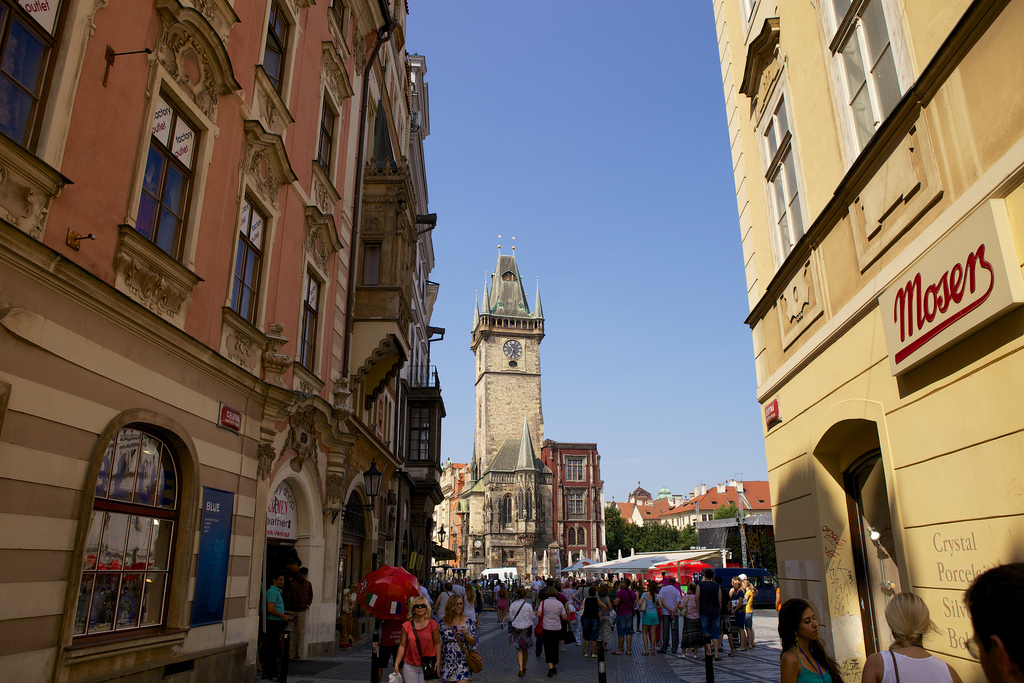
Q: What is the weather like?
A: It is clear.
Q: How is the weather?
A: It is clear.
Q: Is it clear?
A: Yes, it is clear.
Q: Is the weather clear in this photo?
A: Yes, it is clear.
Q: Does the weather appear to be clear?
A: Yes, it is clear.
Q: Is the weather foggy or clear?
A: It is clear.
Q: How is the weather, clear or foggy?
A: It is clear.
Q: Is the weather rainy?
A: No, it is clear.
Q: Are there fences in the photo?
A: No, there are no fences.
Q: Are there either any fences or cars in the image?
A: No, there are no fences or cars.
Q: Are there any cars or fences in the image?
A: No, there are no fences or cars.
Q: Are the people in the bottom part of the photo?
A: Yes, the people are in the bottom of the image.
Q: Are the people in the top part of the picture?
A: No, the people are in the bottom of the image.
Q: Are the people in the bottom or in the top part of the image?
A: The people are in the bottom of the image.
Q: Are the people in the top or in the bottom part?
A: The people are in the bottom of the image.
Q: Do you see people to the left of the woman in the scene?
A: Yes, there are people to the left of the woman.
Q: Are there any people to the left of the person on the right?
A: Yes, there are people to the left of the woman.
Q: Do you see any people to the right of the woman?
A: No, the people are to the left of the woman.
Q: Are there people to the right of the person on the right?
A: No, the people are to the left of the woman.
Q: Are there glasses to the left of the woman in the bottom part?
A: No, there are people to the left of the woman.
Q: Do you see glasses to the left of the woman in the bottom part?
A: No, there are people to the left of the woman.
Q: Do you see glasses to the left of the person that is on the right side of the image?
A: No, there are people to the left of the woman.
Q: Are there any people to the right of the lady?
A: Yes, there are people to the right of the lady.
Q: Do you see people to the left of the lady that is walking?
A: No, the people are to the right of the lady.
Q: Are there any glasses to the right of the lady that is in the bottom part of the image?
A: No, there are people to the right of the lady.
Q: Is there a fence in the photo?
A: No, there are no fences.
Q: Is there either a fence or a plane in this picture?
A: No, there are no fences or airplanes.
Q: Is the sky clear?
A: Yes, the sky is clear.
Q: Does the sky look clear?
A: Yes, the sky is clear.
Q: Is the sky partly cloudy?
A: No, the sky is clear.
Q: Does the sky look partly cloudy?
A: No, the sky is clear.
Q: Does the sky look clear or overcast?
A: The sky is clear.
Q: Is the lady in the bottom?
A: Yes, the lady is in the bottom of the image.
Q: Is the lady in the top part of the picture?
A: No, the lady is in the bottom of the image.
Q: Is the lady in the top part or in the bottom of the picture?
A: The lady is in the bottom of the image.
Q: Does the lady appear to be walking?
A: Yes, the lady is walking.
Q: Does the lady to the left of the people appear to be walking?
A: Yes, the lady is walking.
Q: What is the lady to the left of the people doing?
A: The lady is walking.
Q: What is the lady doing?
A: The lady is walking.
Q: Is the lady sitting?
A: No, the lady is walking.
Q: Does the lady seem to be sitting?
A: No, the lady is walking.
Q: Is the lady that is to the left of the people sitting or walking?
A: The lady is walking.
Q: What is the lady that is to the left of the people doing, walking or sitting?
A: The lady is walking.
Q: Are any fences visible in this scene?
A: No, there are no fences.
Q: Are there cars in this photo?
A: No, there are no cars.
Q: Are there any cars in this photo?
A: No, there are no cars.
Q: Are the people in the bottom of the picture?
A: Yes, the people are in the bottom of the image.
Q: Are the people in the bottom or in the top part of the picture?
A: The people are in the bottom of the image.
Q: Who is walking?
A: The people are walking.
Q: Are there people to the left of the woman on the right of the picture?
A: Yes, there are people to the left of the woman.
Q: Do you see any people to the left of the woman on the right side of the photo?
A: Yes, there are people to the left of the woman.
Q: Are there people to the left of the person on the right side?
A: Yes, there are people to the left of the woman.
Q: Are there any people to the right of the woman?
A: No, the people are to the left of the woman.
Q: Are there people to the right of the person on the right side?
A: No, the people are to the left of the woman.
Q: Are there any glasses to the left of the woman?
A: No, there are people to the left of the woman.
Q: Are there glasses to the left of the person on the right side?
A: No, there are people to the left of the woman.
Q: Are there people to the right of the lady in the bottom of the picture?
A: Yes, there are people to the right of the lady.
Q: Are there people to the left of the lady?
A: No, the people are to the right of the lady.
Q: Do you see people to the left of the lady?
A: No, the people are to the right of the lady.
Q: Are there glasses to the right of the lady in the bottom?
A: No, there are people to the right of the lady.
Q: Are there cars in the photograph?
A: No, there are no cars.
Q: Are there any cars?
A: No, there are no cars.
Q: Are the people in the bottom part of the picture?
A: Yes, the people are in the bottom of the image.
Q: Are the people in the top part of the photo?
A: No, the people are in the bottom of the image.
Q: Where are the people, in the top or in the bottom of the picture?
A: The people are in the bottom of the image.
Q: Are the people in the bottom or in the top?
A: The people are in the bottom of the image.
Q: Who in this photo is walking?
A: The people are walking.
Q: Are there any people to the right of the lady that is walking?
A: Yes, there are people to the right of the lady.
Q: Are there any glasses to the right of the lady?
A: No, there are people to the right of the lady.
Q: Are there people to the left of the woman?
A: Yes, there are people to the left of the woman.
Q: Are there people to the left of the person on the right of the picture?
A: Yes, there are people to the left of the woman.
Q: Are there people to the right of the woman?
A: No, the people are to the left of the woman.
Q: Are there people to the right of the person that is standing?
A: No, the people are to the left of the woman.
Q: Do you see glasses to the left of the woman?
A: No, there are people to the left of the woman.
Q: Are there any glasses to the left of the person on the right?
A: No, there are people to the left of the woman.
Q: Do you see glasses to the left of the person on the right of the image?
A: No, there are people to the left of the woman.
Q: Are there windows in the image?
A: Yes, there is a window.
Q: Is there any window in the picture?
A: Yes, there is a window.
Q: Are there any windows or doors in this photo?
A: Yes, there is a window.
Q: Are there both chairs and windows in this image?
A: No, there is a window but no chairs.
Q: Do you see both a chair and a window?
A: No, there is a window but no chairs.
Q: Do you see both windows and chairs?
A: No, there is a window but no chairs.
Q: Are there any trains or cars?
A: No, there are no cars or trains.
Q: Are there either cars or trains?
A: No, there are no cars or trains.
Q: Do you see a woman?
A: Yes, there is a woman.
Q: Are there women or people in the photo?
A: Yes, there is a woman.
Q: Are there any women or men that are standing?
A: Yes, the woman is standing.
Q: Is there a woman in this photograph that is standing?
A: Yes, there is a woman that is standing.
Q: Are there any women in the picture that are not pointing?
A: Yes, there is a woman that is standing.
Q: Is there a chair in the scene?
A: No, there are no chairs.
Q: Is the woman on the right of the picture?
A: Yes, the woman is on the right of the image.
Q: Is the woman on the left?
A: No, the woman is on the right of the image.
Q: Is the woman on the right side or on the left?
A: The woman is on the right of the image.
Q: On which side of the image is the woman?
A: The woman is on the right of the image.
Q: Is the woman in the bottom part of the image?
A: Yes, the woman is in the bottom of the image.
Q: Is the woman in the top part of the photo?
A: No, the woman is in the bottom of the image.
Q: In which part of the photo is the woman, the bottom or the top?
A: The woman is in the bottom of the image.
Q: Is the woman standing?
A: Yes, the woman is standing.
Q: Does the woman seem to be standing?
A: Yes, the woman is standing.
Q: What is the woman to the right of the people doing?
A: The woman is standing.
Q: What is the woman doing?
A: The woman is standing.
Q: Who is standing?
A: The woman is standing.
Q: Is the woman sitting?
A: No, the woman is standing.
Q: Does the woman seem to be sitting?
A: No, the woman is standing.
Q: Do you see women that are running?
A: No, there is a woman but she is standing.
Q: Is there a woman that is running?
A: No, there is a woman but she is standing.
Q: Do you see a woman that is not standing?
A: No, there is a woman but she is standing.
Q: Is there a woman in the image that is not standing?
A: No, there is a woman but she is standing.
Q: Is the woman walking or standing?
A: The woman is standing.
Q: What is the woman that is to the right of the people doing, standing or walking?
A: The woman is standing.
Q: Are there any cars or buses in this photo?
A: No, there are no cars or buses.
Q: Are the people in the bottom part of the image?
A: Yes, the people are in the bottom of the image.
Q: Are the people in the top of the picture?
A: No, the people are in the bottom of the image.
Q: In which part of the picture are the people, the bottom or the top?
A: The people are in the bottom of the image.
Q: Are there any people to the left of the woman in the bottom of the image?
A: Yes, there are people to the left of the woman.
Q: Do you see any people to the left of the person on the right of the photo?
A: Yes, there are people to the left of the woman.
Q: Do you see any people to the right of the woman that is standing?
A: No, the people are to the left of the woman.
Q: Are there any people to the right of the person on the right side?
A: No, the people are to the left of the woman.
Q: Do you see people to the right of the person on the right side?
A: No, the people are to the left of the woman.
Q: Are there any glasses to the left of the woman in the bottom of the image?
A: No, there are people to the left of the woman.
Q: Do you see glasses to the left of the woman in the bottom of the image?
A: No, there are people to the left of the woman.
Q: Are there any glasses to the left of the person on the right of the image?
A: No, there are people to the left of the woman.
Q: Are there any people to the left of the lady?
A: No, the people are to the right of the lady.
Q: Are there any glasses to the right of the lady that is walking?
A: No, there are people to the right of the lady.